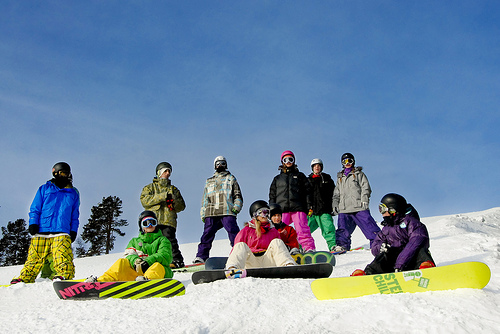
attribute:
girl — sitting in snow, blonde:
[239, 205, 300, 270]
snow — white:
[198, 300, 282, 322]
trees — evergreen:
[4, 220, 130, 262]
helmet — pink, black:
[270, 153, 296, 176]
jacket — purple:
[380, 217, 427, 264]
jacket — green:
[126, 238, 179, 267]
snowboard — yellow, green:
[312, 272, 491, 308]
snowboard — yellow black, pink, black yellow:
[57, 256, 189, 302]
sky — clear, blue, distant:
[249, 7, 318, 26]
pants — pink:
[282, 206, 326, 251]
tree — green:
[83, 185, 125, 248]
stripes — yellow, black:
[98, 278, 185, 303]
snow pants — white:
[226, 236, 315, 286]